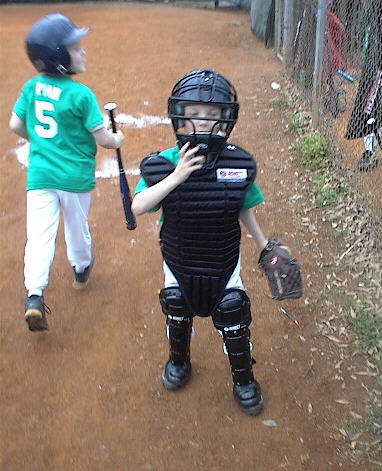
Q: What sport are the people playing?
A: Baseball.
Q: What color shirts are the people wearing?
A: Green.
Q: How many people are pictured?
A: Two.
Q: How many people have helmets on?
A: One.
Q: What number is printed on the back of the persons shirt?
A: Five.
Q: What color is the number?
A: White.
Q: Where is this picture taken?
A: At a Little League game.